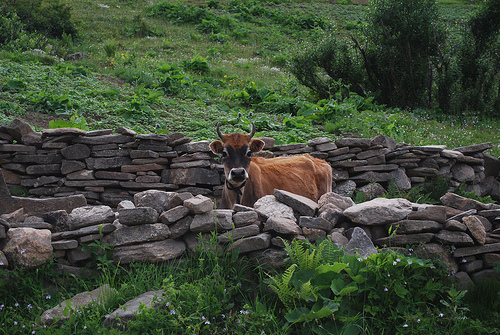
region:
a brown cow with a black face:
[199, 113, 377, 213]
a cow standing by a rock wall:
[184, 105, 392, 250]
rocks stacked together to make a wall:
[51, 120, 211, 211]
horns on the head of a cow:
[206, 114, 278, 151]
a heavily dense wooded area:
[264, 15, 496, 115]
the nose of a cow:
[221, 163, 259, 197]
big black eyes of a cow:
[210, 147, 262, 164]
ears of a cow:
[206, 130, 269, 164]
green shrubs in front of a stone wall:
[276, 220, 466, 322]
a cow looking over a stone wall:
[214, 100, 371, 205]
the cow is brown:
[202, 104, 377, 226]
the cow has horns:
[197, 105, 268, 152]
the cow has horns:
[210, 119, 267, 146]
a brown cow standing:
[210, 118, 330, 208]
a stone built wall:
[1, 118, 496, 208]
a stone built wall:
[0, 188, 499, 294]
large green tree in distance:
[361, 0, 443, 112]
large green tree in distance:
[435, 0, 499, 111]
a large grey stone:
[270, 187, 319, 218]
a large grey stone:
[252, 192, 296, 218]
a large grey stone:
[262, 215, 297, 234]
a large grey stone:
[319, 190, 355, 211]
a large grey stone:
[341, 194, 411, 223]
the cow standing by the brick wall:
[199, 115, 337, 209]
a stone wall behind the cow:
[4, 123, 490, 197]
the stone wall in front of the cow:
[8, 204, 491, 268]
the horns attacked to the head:
[204, 120, 256, 139]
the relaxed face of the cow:
[206, 138, 263, 190]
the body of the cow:
[251, 153, 333, 195]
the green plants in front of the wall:
[126, 250, 463, 334]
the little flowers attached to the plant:
[383, 255, 461, 323]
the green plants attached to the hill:
[19, 25, 338, 135]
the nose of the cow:
[226, 168, 249, 182]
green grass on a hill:
[141, 51, 245, 123]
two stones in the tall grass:
[46, 282, 191, 331]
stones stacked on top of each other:
[75, 184, 184, 276]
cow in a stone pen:
[200, 120, 347, 225]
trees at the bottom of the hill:
[298, 17, 448, 115]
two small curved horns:
[212, 113, 267, 143]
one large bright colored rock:
[0, 225, 55, 270]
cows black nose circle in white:
[211, 159, 258, 190]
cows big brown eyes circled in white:
[220, 144, 260, 164]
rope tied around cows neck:
[224, 176, 252, 204]